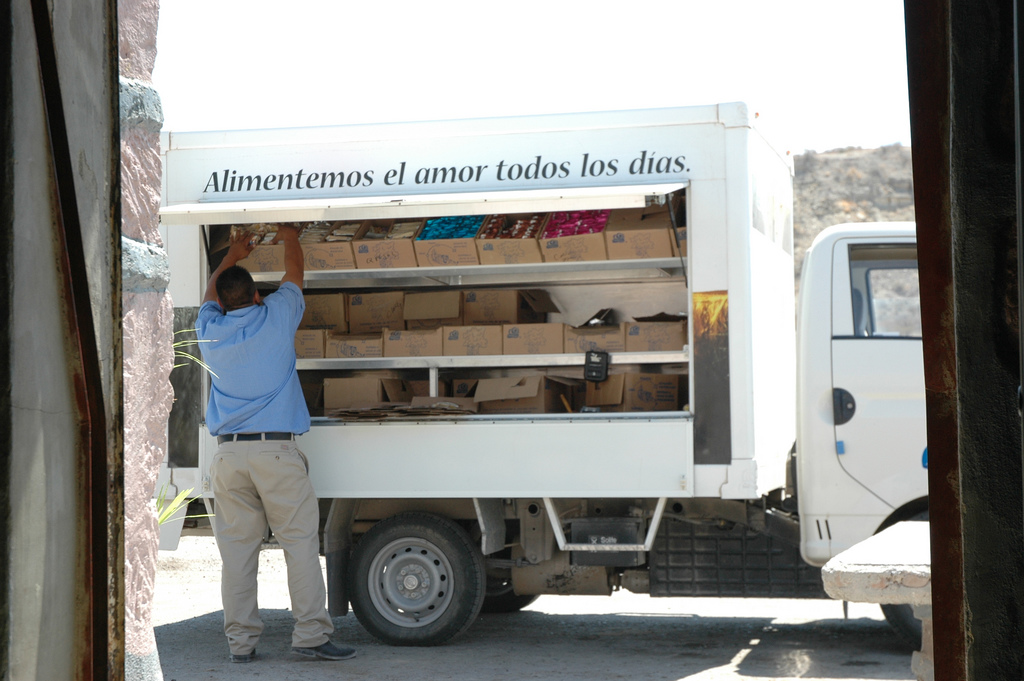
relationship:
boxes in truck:
[210, 201, 689, 416] [177, 117, 925, 619]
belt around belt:
[217, 424, 294, 444] [217, 432, 296, 444]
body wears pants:
[194, 224, 356, 663] [209, 434, 331, 644]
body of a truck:
[164, 82, 806, 521] [160, 125, 777, 496]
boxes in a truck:
[233, 225, 687, 413] [160, 125, 777, 496]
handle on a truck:
[823, 389, 856, 429] [177, 117, 925, 619]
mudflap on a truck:
[320, 504, 347, 619] [177, 117, 925, 619]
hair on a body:
[193, 236, 361, 673] [194, 224, 356, 663]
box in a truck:
[601, 201, 671, 252] [177, 117, 925, 619]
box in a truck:
[544, 201, 608, 258] [177, 117, 925, 619]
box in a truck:
[468, 210, 539, 258] [177, 117, 925, 619]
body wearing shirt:
[194, 224, 356, 663] [183, 288, 324, 472]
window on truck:
[844, 242, 921, 338] [169, 130, 846, 656]